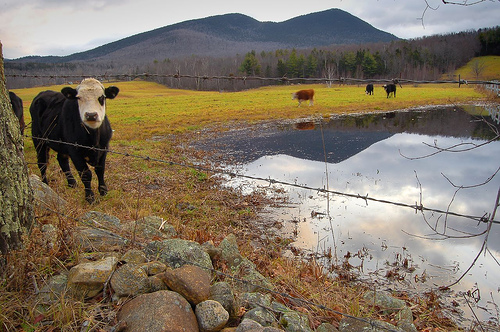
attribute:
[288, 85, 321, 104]
cow — brown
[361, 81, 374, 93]
cow — black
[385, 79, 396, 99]
cow — black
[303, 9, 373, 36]
peak — mountain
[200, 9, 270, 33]
peak — mountain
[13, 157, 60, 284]
trunk — tree's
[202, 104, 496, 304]
pond —  water 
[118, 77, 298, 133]
grass —  green and yellowish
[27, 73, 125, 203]
cow —  Black and white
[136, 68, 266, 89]
fence —  Barbed,   wire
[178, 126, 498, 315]
pond —  with debris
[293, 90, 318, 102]
cow —  Brown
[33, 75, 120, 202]
cow — black, white, tan ,  Mostly black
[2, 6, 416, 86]
hills —  Rolling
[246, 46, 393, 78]
trees —  evergreen,  desiduous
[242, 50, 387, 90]
trees —  Evergreen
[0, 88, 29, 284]
trunk —   Tree's,  peeling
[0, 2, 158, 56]
sky —  Cloudy,   overcast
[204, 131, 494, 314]
reflection — of Cloud 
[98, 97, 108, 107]
black eye —  ONE,   COW's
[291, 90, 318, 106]
cow —  BROWN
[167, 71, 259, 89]
fencing —  BARBED,  WIRE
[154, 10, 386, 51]
ridge —  MOUNTAIN's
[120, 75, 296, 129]
grass —  YELLOW GREEN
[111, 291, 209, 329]
rocks —  BROWN ,  WITH LICHENS 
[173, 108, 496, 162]
pond —  SHALLOW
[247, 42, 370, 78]
trees —  EVERGREEN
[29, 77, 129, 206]
cow —  BLACK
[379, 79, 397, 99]
cow — three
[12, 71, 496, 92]
fence — bobbed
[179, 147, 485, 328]
leaves — old, fallen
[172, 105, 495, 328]
pond — natural, open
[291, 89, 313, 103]
cow — brown, white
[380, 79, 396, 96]
cow — black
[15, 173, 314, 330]
boulders — cluster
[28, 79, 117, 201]
cow — black, white, four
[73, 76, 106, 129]
face —   WHITE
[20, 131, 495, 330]
fence — barb, wired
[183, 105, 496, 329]
water — body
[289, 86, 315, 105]
cow — one, brown, black